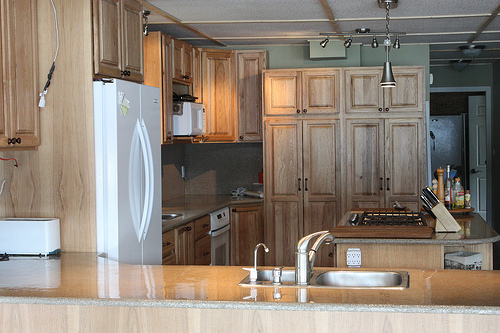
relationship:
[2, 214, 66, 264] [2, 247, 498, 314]
toaster on counter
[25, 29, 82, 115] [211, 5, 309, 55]
cord hanging from ceiling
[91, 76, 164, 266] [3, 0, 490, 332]
fridge in kitchen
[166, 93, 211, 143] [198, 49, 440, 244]
microwave near cabinets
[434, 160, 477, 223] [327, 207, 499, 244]
bottles on top of counter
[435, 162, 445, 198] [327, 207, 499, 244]
peppermill on top of counter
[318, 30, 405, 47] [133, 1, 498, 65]
lights on ceiling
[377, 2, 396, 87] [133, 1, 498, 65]
lights on ceiling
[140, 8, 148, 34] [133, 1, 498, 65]
lights on ceiling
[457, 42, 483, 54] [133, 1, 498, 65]
lights on ceiling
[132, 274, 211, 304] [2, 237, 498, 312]
reflection on counter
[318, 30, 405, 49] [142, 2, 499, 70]
lights on ceiling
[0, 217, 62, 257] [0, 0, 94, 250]
toaster against wall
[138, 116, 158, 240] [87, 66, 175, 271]
handles of refrigerator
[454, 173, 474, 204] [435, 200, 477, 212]
condiment on tray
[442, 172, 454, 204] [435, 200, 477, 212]
condiment on tray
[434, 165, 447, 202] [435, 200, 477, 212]
condiment on tray